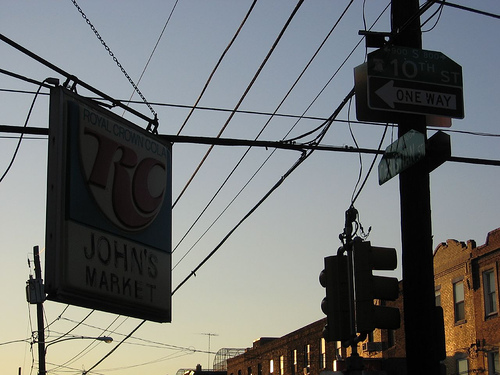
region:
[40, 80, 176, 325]
hanging commercial advertising sign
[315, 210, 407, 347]
hanging black traffic light with no lights showing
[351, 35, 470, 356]
pole with several traffic signs on it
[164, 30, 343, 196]
overhead power lines over a street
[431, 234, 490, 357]
yellow brick building with a window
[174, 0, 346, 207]
blue sky over power lines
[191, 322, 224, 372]
receiving antenna on top of a building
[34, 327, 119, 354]
street light on a utility pole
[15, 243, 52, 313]
transformer hanging on a utility pole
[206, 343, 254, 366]
greenhouse located on roof of a building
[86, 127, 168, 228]
barely visible RC Cola logo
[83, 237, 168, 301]
barely visible John's Market lettering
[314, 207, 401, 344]
traffic light visible in silhouette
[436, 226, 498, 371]
brick facade of a building in setting sun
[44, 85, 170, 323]
almost unreadable hanging sign for a local market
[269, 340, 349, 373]
windows of darkened building being hit by the sun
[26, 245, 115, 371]
streetlight with the lamp protruding over the street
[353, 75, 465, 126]
lower edge of a traffic sign at the corner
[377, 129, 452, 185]
unreadable street or traffic sign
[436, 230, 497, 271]
ornamental top of the old building facade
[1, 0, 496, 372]
Lots of wires criss crossing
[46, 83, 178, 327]
Advertisement hanging from sign hanger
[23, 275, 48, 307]
Transformer on telephone pole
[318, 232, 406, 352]
Traffic light facing the other way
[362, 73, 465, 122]
Oneway sign on the pole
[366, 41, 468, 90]
Street sign attached to pole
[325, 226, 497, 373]
Bright sunshine on the building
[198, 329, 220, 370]
Antenna mounted to a roof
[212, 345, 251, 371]
Glass roof on building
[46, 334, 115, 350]
Street light attached to pole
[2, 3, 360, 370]
black wires in sky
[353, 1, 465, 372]
signs on telephone pole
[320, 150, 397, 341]
two traffic lights on wire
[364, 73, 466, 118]
sign with white arrow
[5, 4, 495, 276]
blue of daytime sky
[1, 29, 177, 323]
sqaure sign on pole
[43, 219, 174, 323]
worn words on sign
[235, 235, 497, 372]
row of windows on building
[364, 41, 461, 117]
street sign on one way sign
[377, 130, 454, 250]
signs on two sides of pole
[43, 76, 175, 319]
sign for market and company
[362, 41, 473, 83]
sign with street name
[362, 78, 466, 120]
sign giving street direction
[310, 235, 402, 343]
traffic lights for street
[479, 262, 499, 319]
verticle window on building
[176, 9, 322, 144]
utility lines strung between poles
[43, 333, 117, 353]
light on pole for street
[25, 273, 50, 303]
box for electrical controls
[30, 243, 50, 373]
post holding light and utility equipment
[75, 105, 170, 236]
beverage name brand on sign